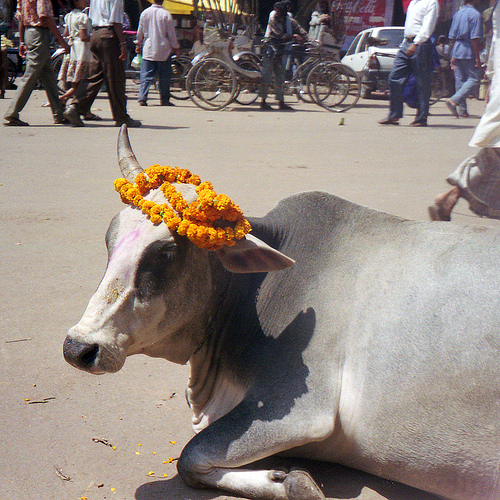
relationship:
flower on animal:
[136, 181, 223, 257] [57, 162, 488, 468]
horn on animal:
[110, 116, 153, 199] [57, 162, 488, 468]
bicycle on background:
[189, 48, 375, 122] [49, 0, 439, 154]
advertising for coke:
[322, 10, 391, 29] [357, 4, 389, 29]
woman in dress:
[61, 9, 98, 103] [67, 23, 90, 63]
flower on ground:
[330, 100, 360, 136] [243, 110, 327, 147]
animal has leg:
[57, 162, 488, 468] [173, 426, 334, 499]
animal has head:
[57, 118, 499, 499] [65, 183, 259, 380]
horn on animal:
[110, 116, 153, 199] [57, 118, 499, 499]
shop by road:
[324, 4, 480, 94] [228, 83, 491, 232]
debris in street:
[214, 101, 371, 166] [39, 103, 449, 202]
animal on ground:
[57, 118, 499, 499] [243, 110, 327, 147]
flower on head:
[136, 181, 223, 257] [65, 183, 259, 380]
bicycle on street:
[189, 48, 375, 122] [39, 103, 449, 202]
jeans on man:
[375, 42, 448, 121] [393, 0, 448, 124]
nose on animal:
[53, 300, 125, 413] [57, 118, 499, 499]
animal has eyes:
[57, 162, 488, 468] [89, 216, 195, 321]